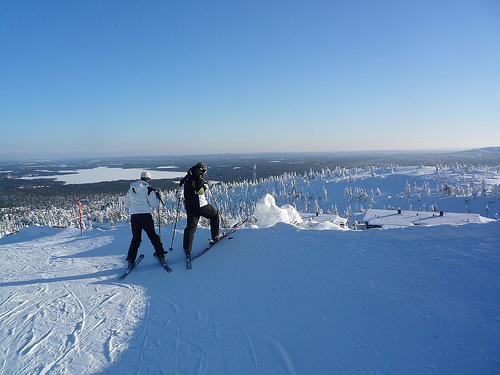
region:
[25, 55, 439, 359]
Two people skiing.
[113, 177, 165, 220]
A long sleeve white jacket.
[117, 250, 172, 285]
A pair of skis on person on left.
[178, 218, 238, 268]
A pair of skis on person on right.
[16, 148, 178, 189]
A body of water in the distant.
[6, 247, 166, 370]
Tracks in the snow.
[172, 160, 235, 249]
Pair of ski poles for person on right.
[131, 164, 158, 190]
White hat on person on left.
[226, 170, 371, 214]
Trees off in the distant.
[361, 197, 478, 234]
The roof of a building.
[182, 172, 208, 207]
skier wearing black, green and white jacket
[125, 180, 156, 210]
skier wearing black and white jacket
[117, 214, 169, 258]
skier wearing black pants jacket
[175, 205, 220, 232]
skier wearing black pants jacket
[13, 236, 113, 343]
white snow with ski tracks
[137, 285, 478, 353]
white snow with ski tracks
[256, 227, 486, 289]
white snow with ski tracks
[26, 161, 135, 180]
calm lake at bottom of hill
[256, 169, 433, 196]
snow covered mountain with trees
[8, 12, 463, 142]
blue sky without clouds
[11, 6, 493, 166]
The sky is blue.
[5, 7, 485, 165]
The sky is clear.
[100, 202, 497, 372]
Shadow on the hill.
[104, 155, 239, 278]
Two people are skiing.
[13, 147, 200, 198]
Water in the background.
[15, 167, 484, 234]
Dead trees on the hills.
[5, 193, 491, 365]
Snow covering the ground.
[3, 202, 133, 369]
The snow is white.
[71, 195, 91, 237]
Safety pole on the cliff.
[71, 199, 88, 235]
Safety pole is orange.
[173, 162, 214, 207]
skier wearing black, white and green jacket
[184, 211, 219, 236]
skier wearing black pants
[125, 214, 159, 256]
skier wearing black pants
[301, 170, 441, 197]
mountain covered with snow and trees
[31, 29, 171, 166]
sunny cloudless day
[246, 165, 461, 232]
trees covered with snow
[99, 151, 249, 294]
two people on skis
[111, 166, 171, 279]
one person wears a white jacket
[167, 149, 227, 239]
one person wears a black jacket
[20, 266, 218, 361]
many ski tracks in the snow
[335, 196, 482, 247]
a building is at the foot of the slope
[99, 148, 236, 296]
both skiiers have ski poles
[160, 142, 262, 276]
one skier almost ready to go down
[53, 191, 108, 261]
orange pole marks the ski slope